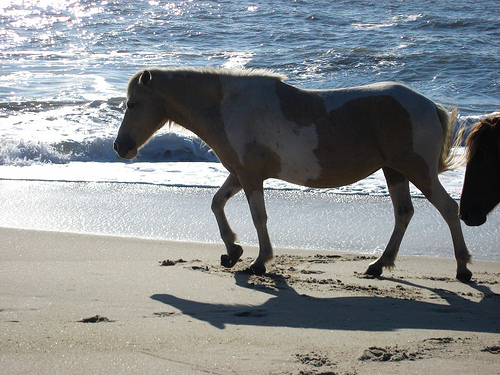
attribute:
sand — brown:
[61, 254, 128, 294]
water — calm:
[2, 8, 492, 195]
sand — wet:
[1, 231, 191, 373]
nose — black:
[101, 136, 122, 156]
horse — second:
[457, 110, 499, 227]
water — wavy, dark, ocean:
[2, 2, 499, 174]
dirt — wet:
[153, 281, 491, 351]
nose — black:
[109, 137, 123, 151]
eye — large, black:
[124, 97, 157, 117]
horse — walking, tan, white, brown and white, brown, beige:
[118, 66, 474, 285]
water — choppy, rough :
[123, 13, 393, 54]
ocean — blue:
[9, 3, 490, 71]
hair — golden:
[187, 86, 445, 211]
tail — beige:
[440, 106, 467, 174]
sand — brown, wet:
[2, 229, 492, 370]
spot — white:
[219, 73, 320, 186]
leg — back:
[362, 167, 417, 276]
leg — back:
[408, 176, 471, 284]